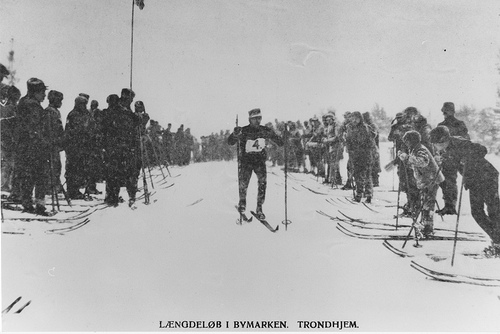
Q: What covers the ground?
A: Snow.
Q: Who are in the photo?
A: People.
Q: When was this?
A: Daytime.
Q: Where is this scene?
A: Mountain.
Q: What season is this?
A: Winter.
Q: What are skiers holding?
A: Ski poles.